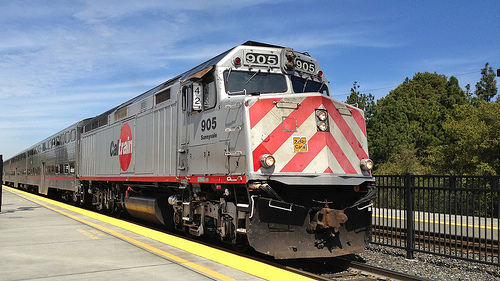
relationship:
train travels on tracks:
[5, 30, 373, 257] [299, 259, 433, 279]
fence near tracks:
[380, 168, 499, 268] [285, 265, 432, 279]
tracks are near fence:
[285, 265, 432, 279] [380, 168, 499, 268]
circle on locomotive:
[117, 124, 134, 171] [0, 41, 374, 256]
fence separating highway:
[380, 168, 499, 268] [368, 203, 498, 255]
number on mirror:
[189, 83, 206, 113] [188, 78, 204, 109]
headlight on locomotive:
[314, 109, 326, 134] [0, 41, 374, 256]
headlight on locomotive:
[258, 154, 276, 167] [0, 41, 374, 256]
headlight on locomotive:
[358, 160, 372, 170] [0, 41, 374, 256]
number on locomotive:
[242, 53, 276, 70] [0, 41, 374, 256]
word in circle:
[115, 137, 135, 158] [117, 124, 136, 167]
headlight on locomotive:
[367, 160, 374, 168] [0, 41, 374, 256]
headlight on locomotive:
[265, 156, 275, 166] [0, 41, 374, 256]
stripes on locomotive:
[247, 92, 371, 179] [0, 41, 374, 256]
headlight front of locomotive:
[313, 108, 327, 132] [0, 41, 374, 256]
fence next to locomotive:
[380, 168, 499, 268] [0, 41, 374, 256]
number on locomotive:
[191, 84, 203, 111] [0, 41, 374, 256]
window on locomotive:
[49, 138, 59, 148] [0, 41, 374, 256]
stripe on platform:
[3, 185, 326, 280] [2, 181, 335, 278]